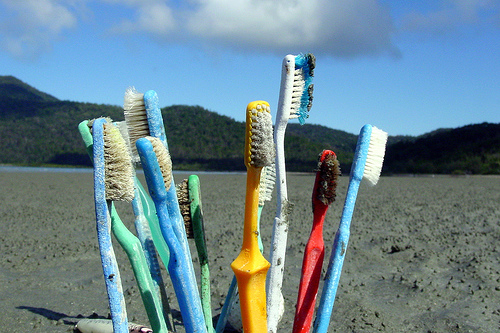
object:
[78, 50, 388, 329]
toothbrushes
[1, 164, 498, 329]
beach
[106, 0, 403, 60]
cloud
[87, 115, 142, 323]
toothbrush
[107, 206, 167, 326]
toothbrush handle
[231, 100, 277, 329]
toothbrush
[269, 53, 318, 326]
toothbrush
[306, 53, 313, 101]
sand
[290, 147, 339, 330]
toothbrush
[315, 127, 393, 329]
toothbrush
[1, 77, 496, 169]
hill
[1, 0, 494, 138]
sky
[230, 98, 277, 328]
tooth brush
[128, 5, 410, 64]
cloud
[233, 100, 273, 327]
toothbrush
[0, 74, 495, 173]
mountain range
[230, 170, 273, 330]
handle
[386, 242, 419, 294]
rocks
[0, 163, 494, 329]
sand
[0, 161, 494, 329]
area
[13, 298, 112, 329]
shadow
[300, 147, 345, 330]
toothbrush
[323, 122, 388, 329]
toothbrush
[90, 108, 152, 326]
toothbrush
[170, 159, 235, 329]
toothbrush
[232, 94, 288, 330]
toothbrush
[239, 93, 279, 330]
toothbrush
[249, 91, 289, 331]
toothbrush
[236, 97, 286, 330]
toothbrush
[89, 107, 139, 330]
toothbrush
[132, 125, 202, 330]
toothbrush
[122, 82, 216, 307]
toothbrush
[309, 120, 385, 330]
toothbrush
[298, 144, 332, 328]
toothbrush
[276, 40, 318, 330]
toothbrush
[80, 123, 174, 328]
toothbrush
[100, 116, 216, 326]
toothbrush